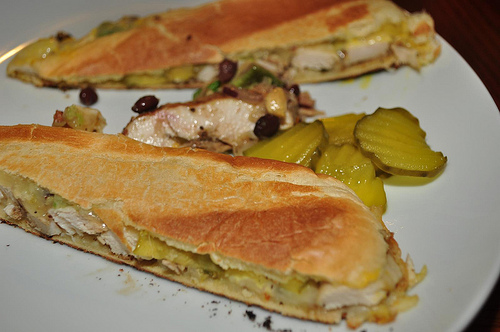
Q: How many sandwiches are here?
A: Two.